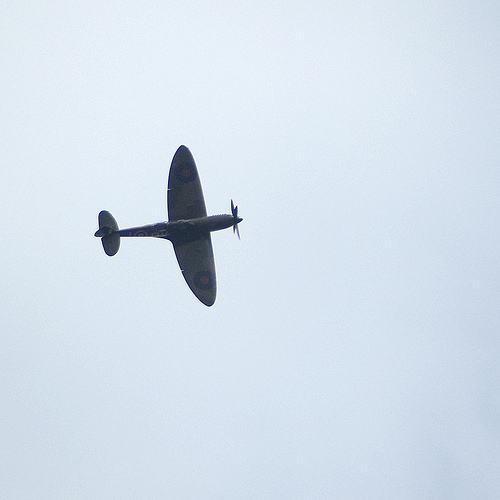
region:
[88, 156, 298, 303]
the plane is flying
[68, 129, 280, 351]
a jet plane in the sky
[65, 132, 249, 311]
gray airplane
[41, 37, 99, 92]
white clouds in blue sky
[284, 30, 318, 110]
white clouds in blue sky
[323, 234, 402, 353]
white clouds in blue sky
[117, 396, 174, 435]
white clouds in blue sky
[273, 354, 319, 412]
white clouds in blue sky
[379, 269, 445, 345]
white clouds in blue sky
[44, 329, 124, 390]
white clouds in blue sky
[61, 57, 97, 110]
white clouds in blue sky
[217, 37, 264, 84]
white clouds in blue sky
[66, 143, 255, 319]
airplane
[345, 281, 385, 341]
white clouds in blue sky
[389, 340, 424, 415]
white clouds in blue sky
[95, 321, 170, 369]
white clouds in blue sky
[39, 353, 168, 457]
white clouds in blue sky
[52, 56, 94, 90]
white clouds in blue sky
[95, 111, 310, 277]
plane in the air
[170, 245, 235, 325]
wing of the plane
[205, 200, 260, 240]
propellor on the plane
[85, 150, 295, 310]
plane in the sky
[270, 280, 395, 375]
blue sky in the background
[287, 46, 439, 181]
sky behind the plane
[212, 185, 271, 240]
front part of the plane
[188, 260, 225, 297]
design on the plane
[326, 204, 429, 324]
sky with no clouds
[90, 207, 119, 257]
Tail of the airplane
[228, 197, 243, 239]
Propeller of the airplane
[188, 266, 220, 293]
Insignia of the right wing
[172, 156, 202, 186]
Insignia of the left wing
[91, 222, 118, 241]
Steering rudder of the airplane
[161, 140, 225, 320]
Wings of the airplane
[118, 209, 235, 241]
Body of the airplane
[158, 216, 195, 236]
Cockpit of the airplane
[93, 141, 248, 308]
Airplane flying sideways